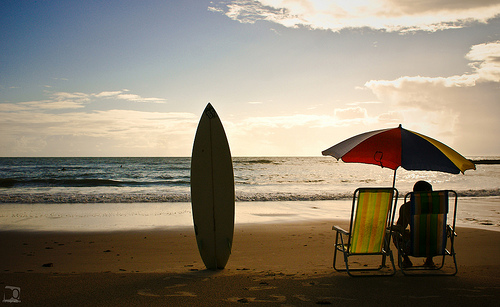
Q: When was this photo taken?
A: During the daylight.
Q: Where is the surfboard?
A: Standing in the sand.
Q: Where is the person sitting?
A: In a chair under an umbrella.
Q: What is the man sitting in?
A: Chair.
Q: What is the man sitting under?
A: Umbrella.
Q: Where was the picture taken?
A: Beach.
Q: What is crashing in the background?
A: Waves.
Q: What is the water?
A: Ocean.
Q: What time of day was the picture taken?
A: Evening.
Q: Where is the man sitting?
A: On the beach.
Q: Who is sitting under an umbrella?
A: A man.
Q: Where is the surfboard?
A: In the sand.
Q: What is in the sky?
A: Clouds.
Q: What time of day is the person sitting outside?
A: During daylight hours.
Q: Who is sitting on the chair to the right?
A: A man.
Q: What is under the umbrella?
A: Two chairs and a person.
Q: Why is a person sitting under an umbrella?
A: Protection from the sun.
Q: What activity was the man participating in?
A: Surfing.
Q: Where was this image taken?
A: A beach.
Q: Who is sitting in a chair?
A: A person.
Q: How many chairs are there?
A: Two.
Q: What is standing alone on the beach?
A: A surfboard.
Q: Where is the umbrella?
A: Above the chairs.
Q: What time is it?
A: Daytime.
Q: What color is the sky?
A: Blue.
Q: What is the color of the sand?
A: Brown.